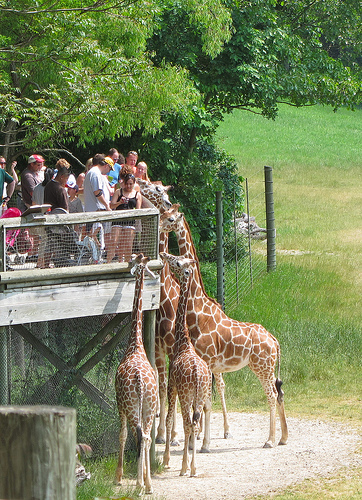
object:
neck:
[129, 276, 143, 342]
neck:
[174, 281, 191, 345]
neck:
[180, 228, 203, 294]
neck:
[159, 210, 169, 271]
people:
[65, 183, 83, 244]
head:
[139, 180, 172, 211]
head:
[136, 162, 146, 177]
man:
[83, 156, 115, 262]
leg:
[214, 373, 230, 439]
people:
[108, 174, 143, 263]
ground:
[212, 106, 362, 500]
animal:
[111, 252, 160, 496]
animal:
[158, 249, 213, 480]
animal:
[158, 201, 290, 452]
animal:
[137, 175, 196, 443]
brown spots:
[121, 365, 137, 396]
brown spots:
[178, 358, 192, 380]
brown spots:
[164, 283, 177, 305]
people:
[44, 159, 76, 267]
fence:
[218, 165, 273, 312]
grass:
[204, 87, 360, 408]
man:
[21, 155, 44, 269]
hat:
[28, 154, 46, 164]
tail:
[273, 345, 285, 406]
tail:
[192, 365, 202, 425]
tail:
[134, 371, 145, 457]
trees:
[128, 85, 254, 275]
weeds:
[253, 260, 361, 330]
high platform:
[0, 194, 159, 325]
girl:
[33, 167, 53, 269]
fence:
[1, 208, 161, 460]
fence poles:
[265, 165, 277, 273]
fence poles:
[245, 177, 253, 289]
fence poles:
[232, 187, 240, 305]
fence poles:
[213, 190, 224, 313]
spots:
[219, 324, 249, 355]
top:
[116, 188, 139, 219]